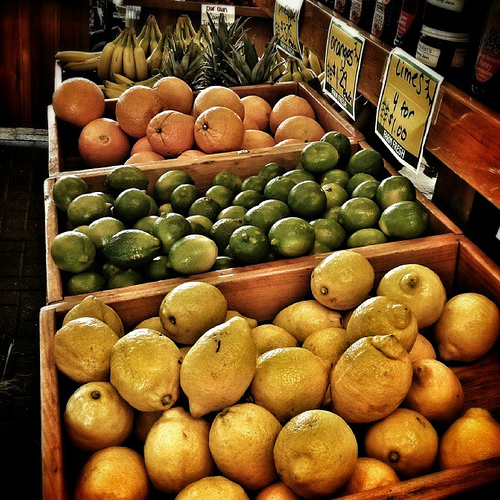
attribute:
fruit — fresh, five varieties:
[66, 17, 499, 497]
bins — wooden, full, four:
[38, 1, 499, 497]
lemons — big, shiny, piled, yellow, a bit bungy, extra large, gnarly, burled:
[58, 255, 497, 500]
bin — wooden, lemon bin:
[34, 233, 499, 500]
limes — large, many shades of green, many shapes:
[52, 139, 424, 288]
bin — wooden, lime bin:
[15, 125, 449, 276]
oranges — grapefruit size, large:
[67, 92, 324, 164]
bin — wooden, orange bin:
[35, 79, 362, 177]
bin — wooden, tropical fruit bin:
[41, 34, 330, 114]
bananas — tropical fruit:
[52, 10, 198, 99]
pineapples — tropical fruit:
[162, 11, 289, 87]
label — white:
[411, 39, 443, 66]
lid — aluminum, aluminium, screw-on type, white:
[418, 19, 472, 42]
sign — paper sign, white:
[202, 3, 236, 31]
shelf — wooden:
[259, 3, 499, 218]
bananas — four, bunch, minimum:
[98, 23, 151, 81]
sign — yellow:
[369, 43, 445, 173]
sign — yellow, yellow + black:
[318, 30, 367, 106]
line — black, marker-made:
[209, 336, 229, 355]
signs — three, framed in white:
[272, 0, 443, 171]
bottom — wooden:
[388, 317, 499, 441]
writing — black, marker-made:
[371, 59, 433, 139]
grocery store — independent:
[3, 1, 499, 500]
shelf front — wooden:
[252, 0, 499, 241]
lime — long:
[95, 224, 168, 267]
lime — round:
[285, 176, 330, 218]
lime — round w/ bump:
[263, 215, 324, 257]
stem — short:
[151, 123, 168, 135]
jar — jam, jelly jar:
[420, 1, 476, 33]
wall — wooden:
[0, 0, 89, 140]